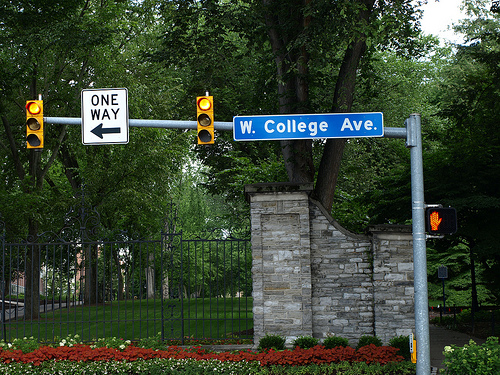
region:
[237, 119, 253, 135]
The letter is white.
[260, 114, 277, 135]
The letter is white.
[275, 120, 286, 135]
The letter is white.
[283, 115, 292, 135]
The letter is white.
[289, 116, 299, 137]
The letter is white.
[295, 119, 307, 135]
The letter is white.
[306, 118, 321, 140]
The letter is white.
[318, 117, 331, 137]
The letter is white.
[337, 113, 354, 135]
The letter is white.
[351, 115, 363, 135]
The letter is white.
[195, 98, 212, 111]
Orange light signal on traffic light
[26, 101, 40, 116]
Orange light signal on traffic light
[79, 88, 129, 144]
Black and white traffic sign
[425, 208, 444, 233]
Red hand is illuminated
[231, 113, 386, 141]
Blue and white street sign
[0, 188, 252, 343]
Black gate behind light post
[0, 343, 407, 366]
Red flowers behind light post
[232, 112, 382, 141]
Blue and white street sign next to traffic signal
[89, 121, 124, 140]
Black arrow on black and white traffic sign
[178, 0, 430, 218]
Tree behind brick wall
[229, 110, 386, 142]
The sign is blue.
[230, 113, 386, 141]
The lettering is white.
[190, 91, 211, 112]
The light is yellow.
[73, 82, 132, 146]
The sign is white.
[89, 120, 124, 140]
The arrow is black.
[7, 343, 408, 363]
The flowers are red.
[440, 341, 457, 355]
The flower is white.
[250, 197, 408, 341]
The wall is brick.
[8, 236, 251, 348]
The fence is metal.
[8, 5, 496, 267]
The trees are leafy.